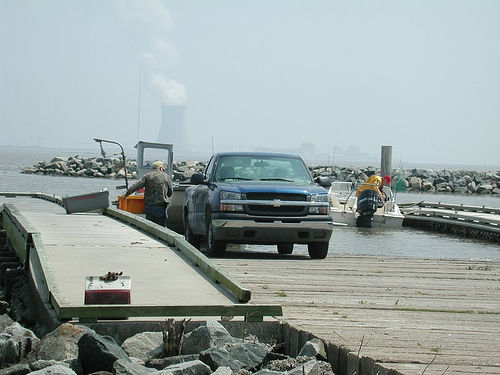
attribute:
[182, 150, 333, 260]
pick-up truck — blue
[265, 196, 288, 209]
logo — Chevy brand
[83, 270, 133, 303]
ice chest — red, white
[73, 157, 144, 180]
jetty — rocks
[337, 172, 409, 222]
boat — small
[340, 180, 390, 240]
boat — small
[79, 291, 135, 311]
cooler — red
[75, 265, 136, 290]
top — white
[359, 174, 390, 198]
rain coat — yellow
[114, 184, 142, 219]
container — orange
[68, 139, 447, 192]
rocks — large, grey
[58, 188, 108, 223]
container — grey, large, plastic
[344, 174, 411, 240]
boat — small, white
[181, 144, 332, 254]
pickup — blue, a Chevy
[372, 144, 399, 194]
pole — short, wood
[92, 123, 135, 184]
pole — bent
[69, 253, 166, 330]
cooler — red, white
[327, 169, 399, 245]
boat — white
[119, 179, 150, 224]
container — orange, box shaped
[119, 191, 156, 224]
container — orange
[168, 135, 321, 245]
truck — blue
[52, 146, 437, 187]
rocks — large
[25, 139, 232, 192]
rocks — large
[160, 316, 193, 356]
tree stump — small 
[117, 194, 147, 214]
container — orange 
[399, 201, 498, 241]
dock — narrow 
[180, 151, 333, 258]
truck — blue, parked 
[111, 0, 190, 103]
smoke — thick 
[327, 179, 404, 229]
boat — white , small 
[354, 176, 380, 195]
coat — gold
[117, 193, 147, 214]
crane — orange 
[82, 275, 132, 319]
box — pink and white, small 